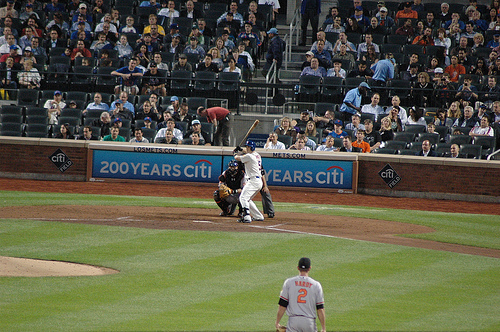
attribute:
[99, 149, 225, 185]
sign — blue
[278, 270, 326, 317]
shirt — man's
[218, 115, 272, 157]
bat — wooden, baseball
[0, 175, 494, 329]
baseball field — green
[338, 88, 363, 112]
shirt — blue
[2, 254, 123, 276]
pitchers mound — dirt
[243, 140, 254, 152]
helmet — hard, blue, batters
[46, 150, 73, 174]
triangle — black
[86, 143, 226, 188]
window — black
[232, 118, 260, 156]
bat — wooden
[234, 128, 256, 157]
helmet — blue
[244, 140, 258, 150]
cap — blue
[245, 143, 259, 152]
head — man's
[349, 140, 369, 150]
shirt — orange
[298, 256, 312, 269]
hat — black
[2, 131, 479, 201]
wall — brick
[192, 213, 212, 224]
home plate — white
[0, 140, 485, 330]
game — baseball game